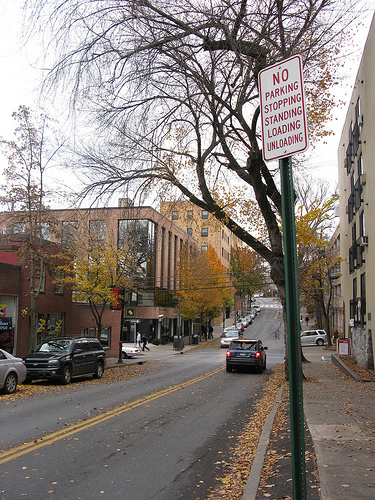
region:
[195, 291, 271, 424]
a car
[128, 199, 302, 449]
a car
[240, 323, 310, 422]
a car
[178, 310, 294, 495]
a car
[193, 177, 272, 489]
a car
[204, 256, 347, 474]
a car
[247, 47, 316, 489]
this is a sign post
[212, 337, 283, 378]
this is a car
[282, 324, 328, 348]
this is a car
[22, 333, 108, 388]
this is a car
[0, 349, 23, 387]
this is a car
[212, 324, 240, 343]
this is a car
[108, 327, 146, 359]
this is a car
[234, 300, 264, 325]
these are cars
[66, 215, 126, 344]
this is a tree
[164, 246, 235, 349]
this is a tree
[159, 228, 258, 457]
a car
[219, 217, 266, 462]
a car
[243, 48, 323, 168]
A RED AND WHITE STREET SIGN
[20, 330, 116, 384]
A PARKED BLACK SUV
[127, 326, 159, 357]
TWO PEOPLE WALKING ON THE SIDEWALK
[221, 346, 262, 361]
A CARS REAR BRAKE LIGHTS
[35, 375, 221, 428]
YELLOW STREET MARKINGS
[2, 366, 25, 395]
A CARS REAR TIRE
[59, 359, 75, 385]
AN SUV'S FRONT TIRE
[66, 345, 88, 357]
A SIDE VIEW MIRROR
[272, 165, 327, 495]
A GREEN SIGN POLE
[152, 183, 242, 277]
A PICTURE OF A BUILDING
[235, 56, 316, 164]
no parking sign on sidewalk.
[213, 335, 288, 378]
a car stopping at the end of a road.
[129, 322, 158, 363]
a person walking down a street.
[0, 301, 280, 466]
a double yellow line.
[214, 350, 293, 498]
leaves on a white line.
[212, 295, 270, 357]
a row of parked cars.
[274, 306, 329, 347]
a white suv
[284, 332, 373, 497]
a sidewalk near buildings.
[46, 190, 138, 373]
a tree with lots of leaves.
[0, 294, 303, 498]
a road near buildings.